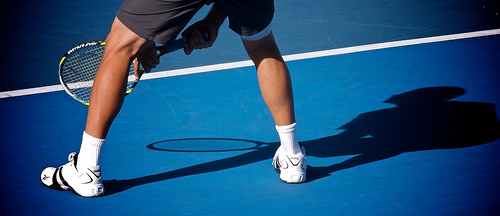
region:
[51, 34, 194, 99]
the tennis racket the man is holding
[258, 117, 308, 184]
the man's shoe and sock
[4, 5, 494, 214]
the blue tennis court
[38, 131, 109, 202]
the other shoe and sock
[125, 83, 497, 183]
the shadow of the man and tennis racket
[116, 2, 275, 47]
the man's black shorts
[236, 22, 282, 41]
the white wrap around the man's leg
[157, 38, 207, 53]
the bottom of the racket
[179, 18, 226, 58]
the man's right hand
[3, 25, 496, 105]
the white line on the court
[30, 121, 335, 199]
White socks and black and white shoes on tennis players feet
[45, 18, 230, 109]
Tennis racket in tennis players hands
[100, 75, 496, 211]
Shadow of tennis player holding a racket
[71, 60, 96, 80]
Strings on a tennis racket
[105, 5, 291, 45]
Black shorts worn by a tennis player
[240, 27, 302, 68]
Shadow behind tennis players right knee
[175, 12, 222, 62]
Tennis players right hand holding racket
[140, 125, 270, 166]
Shadow of tennis racket on court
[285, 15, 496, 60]
White line on tennis court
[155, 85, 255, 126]
Blue surface of tennis court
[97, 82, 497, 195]
The shade of a tennis player.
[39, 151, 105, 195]
The left sneaker of a tennis player.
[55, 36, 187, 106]
The racket of a tennis player.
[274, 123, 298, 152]
The right sock of a tennis player.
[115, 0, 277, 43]
The black short of a tennis player.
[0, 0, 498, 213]
A part of a tennis court.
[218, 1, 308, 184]
The right foot of the tennis player.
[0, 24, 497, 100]
The white line separating the player from the court.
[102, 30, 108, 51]
The knee of a tennis player.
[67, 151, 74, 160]
The shoe lace of a tennis player.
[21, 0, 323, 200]
tennis player standing on a court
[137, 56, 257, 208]
blue tennis court with white line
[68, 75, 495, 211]
shadow of a tennis player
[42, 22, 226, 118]
tennis racket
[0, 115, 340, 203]
white and black tennis shoes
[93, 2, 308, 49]
black tennis shorts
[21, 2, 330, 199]
male tennis player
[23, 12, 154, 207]
man with a muscular leg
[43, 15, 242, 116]
two hands on a tennis racket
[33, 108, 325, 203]
tennis shoes with white socks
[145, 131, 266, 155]
Shadow of tennis racket.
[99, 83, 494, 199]
Shadow of tennis player.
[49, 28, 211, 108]
Tennis racket being held.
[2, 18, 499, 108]
White lines on the tennis court.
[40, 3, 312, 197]
Tennis player on court.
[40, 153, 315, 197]
Tennis shoes on the player.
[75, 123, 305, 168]
White socks of the tennis player.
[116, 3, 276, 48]
Gray shorts on the tennis player.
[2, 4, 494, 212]
Blue tennis court in color.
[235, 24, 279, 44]
Support bandage on player.